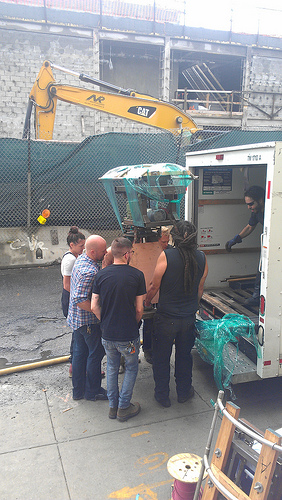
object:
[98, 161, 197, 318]
equipment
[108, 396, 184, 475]
concrete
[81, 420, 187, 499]
stains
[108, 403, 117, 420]
boot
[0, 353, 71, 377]
hose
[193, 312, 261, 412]
plastic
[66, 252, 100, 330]
shirt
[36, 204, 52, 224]
caterpillar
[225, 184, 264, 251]
man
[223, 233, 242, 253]
glove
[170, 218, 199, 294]
dreadlock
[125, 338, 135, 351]
keys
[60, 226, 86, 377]
woman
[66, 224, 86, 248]
bun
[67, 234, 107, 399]
man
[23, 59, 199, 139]
machine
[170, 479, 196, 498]
wire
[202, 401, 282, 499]
pallet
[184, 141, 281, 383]
truck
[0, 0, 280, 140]
building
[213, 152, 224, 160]
light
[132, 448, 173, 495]
writing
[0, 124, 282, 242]
fence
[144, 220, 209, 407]
people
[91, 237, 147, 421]
men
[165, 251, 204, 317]
back